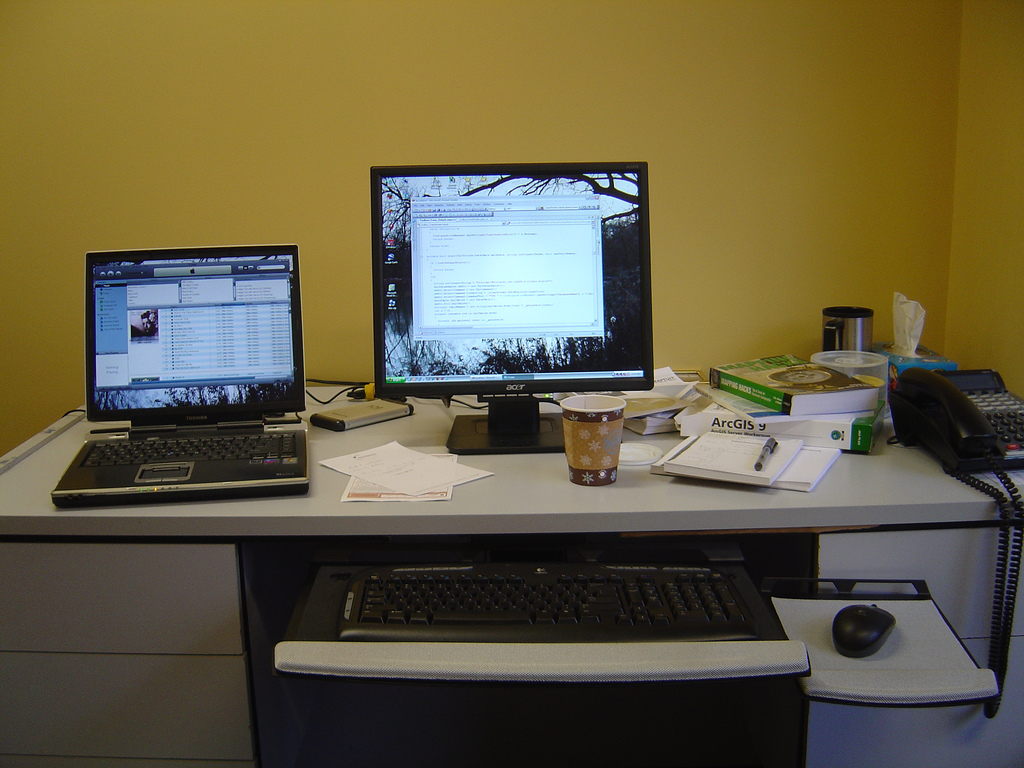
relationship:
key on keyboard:
[523, 595, 566, 630] [269, 546, 814, 680]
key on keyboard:
[550, 601, 609, 630] [269, 546, 814, 680]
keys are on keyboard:
[356, 574, 400, 623] [269, 546, 814, 680]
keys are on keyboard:
[401, 562, 451, 623] [269, 546, 814, 680]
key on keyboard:
[402, 579, 433, 603] [335, 540, 783, 646]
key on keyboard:
[529, 588, 562, 608] [337, 547, 776, 649]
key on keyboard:
[544, 562, 577, 591] [328, 554, 765, 645]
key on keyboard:
[589, 577, 628, 604] [335, 553, 770, 638]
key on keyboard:
[438, 569, 475, 606] [335, 540, 783, 646]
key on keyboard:
[430, 584, 459, 613] [326, 532, 770, 639]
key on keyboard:
[725, 592, 762, 621] [328, 554, 765, 645]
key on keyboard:
[609, 573, 651, 597] [328, 554, 765, 645]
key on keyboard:
[501, 588, 545, 623] [328, 543, 761, 634]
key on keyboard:
[482, 599, 530, 634] [335, 553, 770, 638]